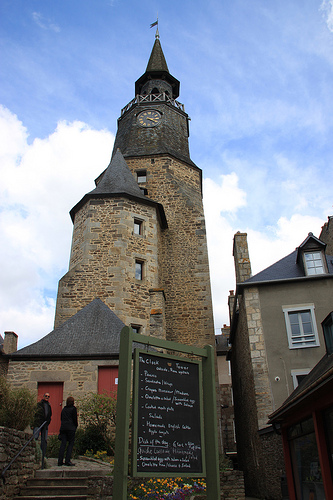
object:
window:
[302, 246, 327, 277]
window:
[290, 370, 310, 388]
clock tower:
[50, 18, 224, 459]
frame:
[132, 347, 205, 481]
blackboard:
[139, 354, 202, 474]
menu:
[138, 356, 201, 475]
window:
[303, 250, 325, 274]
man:
[56, 397, 78, 467]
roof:
[144, 38, 172, 70]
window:
[281, 296, 321, 352]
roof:
[265, 345, 333, 421]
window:
[287, 419, 326, 497]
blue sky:
[37, 22, 132, 65]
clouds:
[9, 115, 85, 181]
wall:
[115, 85, 165, 128]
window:
[130, 321, 142, 334]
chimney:
[233, 231, 252, 279]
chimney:
[229, 289, 234, 294]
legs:
[59, 439, 65, 462]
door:
[96, 363, 118, 408]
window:
[132, 217, 143, 236]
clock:
[137, 110, 161, 127]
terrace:
[114, 94, 185, 116]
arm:
[36, 406, 42, 425]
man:
[32, 392, 51, 456]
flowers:
[195, 488, 203, 497]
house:
[224, 227, 333, 500]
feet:
[65, 459, 73, 467]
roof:
[11, 298, 159, 363]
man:
[33, 391, 52, 466]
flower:
[158, 480, 165, 486]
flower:
[182, 485, 187, 490]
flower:
[138, 482, 144, 487]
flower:
[174, 477, 180, 482]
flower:
[156, 490, 162, 495]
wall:
[0, 429, 35, 496]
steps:
[14, 465, 87, 498]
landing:
[35, 453, 111, 475]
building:
[0, 12, 333, 499]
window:
[134, 259, 148, 283]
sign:
[130, 346, 208, 478]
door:
[36, 382, 62, 433]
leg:
[40, 431, 45, 462]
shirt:
[35, 399, 52, 424]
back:
[61, 406, 76, 434]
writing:
[135, 352, 201, 469]